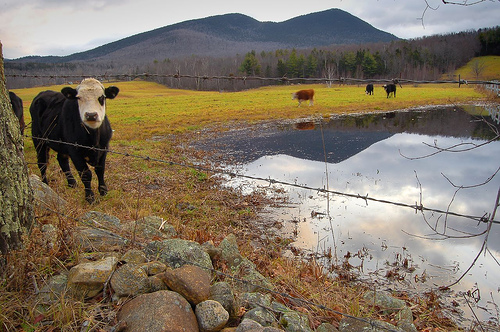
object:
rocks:
[183, 292, 235, 331]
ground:
[0, 78, 500, 332]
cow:
[288, 85, 321, 110]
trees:
[339, 48, 360, 79]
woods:
[0, 22, 500, 92]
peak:
[291, 0, 389, 36]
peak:
[188, 4, 269, 41]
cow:
[10, 59, 143, 203]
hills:
[2, 6, 442, 86]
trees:
[371, 46, 386, 78]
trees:
[273, 45, 290, 90]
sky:
[0, 2, 500, 60]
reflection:
[200, 107, 499, 293]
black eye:
[90, 92, 114, 110]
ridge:
[154, 3, 387, 51]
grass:
[8, 75, 482, 143]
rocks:
[111, 267, 209, 332]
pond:
[173, 102, 496, 327]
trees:
[317, 42, 339, 88]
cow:
[379, 81, 407, 102]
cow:
[360, 80, 380, 97]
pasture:
[1, 75, 497, 233]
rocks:
[61, 244, 127, 306]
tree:
[0, 44, 40, 304]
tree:
[240, 49, 260, 85]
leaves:
[280, 64, 291, 71]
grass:
[1, 79, 480, 328]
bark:
[1, 47, 44, 279]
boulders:
[145, 250, 235, 308]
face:
[70, 76, 109, 129]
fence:
[0, 69, 495, 332]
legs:
[30, 136, 55, 186]